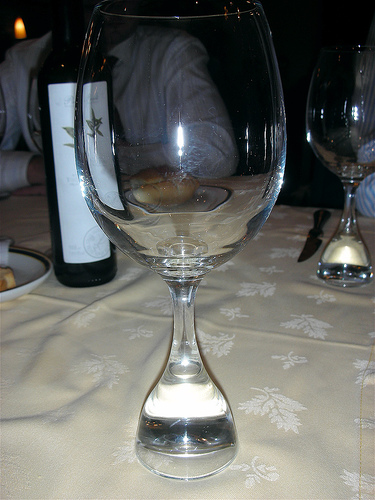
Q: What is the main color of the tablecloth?
A: Beige.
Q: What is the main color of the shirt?
A: Gray.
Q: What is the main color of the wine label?
A: White.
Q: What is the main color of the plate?
A: White.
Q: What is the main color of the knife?
A: Gray.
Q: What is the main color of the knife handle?
A: Gray.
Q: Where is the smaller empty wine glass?
A: To the right of a larger one.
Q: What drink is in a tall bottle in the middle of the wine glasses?
A: Wine.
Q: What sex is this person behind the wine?
A: Male.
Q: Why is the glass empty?
A: No one poured a drink in it.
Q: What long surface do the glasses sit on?
A: Table.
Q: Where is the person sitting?
A: In the back.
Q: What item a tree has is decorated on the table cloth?
A: Leaves.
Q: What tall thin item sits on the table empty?
A: Wine glass.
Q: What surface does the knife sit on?
A: Table.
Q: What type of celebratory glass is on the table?
A: Wine glass.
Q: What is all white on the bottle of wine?
A: Label.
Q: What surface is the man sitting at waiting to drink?
A: Table.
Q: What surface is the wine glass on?
A: Table.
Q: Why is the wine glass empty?
A: There's no wine in it.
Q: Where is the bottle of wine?
A: On a table.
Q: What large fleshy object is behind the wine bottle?
A: A man.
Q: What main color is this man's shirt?
A: White.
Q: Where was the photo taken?
A: At a restaurant.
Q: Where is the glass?
A: On the table.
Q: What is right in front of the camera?
A: Wine glass.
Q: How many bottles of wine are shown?
A: 1.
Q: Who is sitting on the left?
A: A man.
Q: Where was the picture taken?
A: At a restaurant.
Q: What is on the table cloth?
A: Leaves.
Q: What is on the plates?
A: Bread.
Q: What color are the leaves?
A: White.